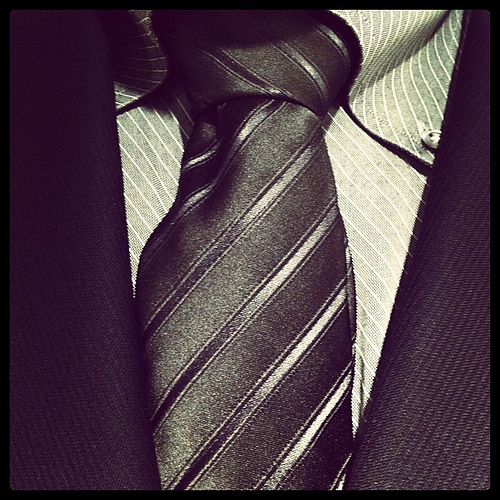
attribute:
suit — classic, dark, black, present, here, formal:
[40, 59, 201, 479]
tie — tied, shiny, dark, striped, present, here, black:
[193, 108, 307, 326]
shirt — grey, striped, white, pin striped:
[133, 119, 181, 203]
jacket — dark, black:
[429, 183, 499, 447]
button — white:
[415, 129, 455, 162]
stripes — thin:
[349, 148, 400, 257]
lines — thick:
[190, 152, 296, 299]